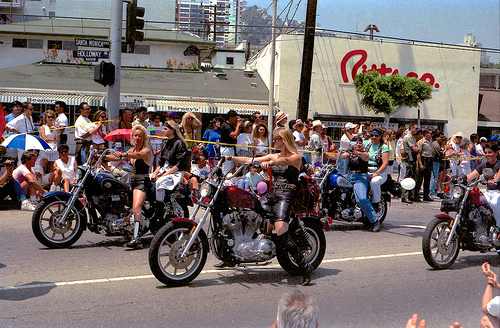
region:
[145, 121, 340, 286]
a woman riding a motorcycle.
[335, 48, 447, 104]
a sign for a store.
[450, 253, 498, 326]
a pair of hands clapping.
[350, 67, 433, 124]
a tree with lots of green leaves.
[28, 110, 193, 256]
a woman riding a harley.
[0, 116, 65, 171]
a blue and white umbrella.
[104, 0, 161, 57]
a black traffic signal.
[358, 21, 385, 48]
an object on top of a roof.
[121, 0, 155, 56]
a traffic light on the side of a road.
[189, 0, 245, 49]
the top of a building.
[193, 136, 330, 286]
woman riding red motorcycle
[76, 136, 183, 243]
woman riding blue motorcycle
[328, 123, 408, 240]
couple riding blue motorcycle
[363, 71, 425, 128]
small green leafy tree in background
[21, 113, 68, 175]
person holding blue and white umbrella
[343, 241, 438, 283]
white line in the street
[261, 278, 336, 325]
back of guys balding head with gray hair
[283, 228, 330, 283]
woman wearing tall black boots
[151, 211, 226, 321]
silver wheel inside of black tire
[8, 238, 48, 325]
shadow of someone standing in the street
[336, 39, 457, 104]
the letters are red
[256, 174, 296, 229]
woman is wearing skirt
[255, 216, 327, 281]
woman wearing black boots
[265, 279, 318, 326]
man's hair is gray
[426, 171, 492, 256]
the motorcycle is red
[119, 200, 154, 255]
woman wearing cowboy boots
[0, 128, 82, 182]
person holding blue and white umbrella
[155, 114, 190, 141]
a person wearing bandana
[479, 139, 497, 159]
the person is smiling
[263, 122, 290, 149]
woman is wearing sunglasses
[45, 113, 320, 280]
women on motorcycles going slow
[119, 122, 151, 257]
blonde in leather and boots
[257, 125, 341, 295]
blonde in leather and sunglasses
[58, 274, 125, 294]
white line in the middle of the road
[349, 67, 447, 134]
green tree on the side of the road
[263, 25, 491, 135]
white building on the side of the road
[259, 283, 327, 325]
top of a balding guy's head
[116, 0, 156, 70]
street light on a pole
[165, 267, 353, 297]
shadow of a motorcycle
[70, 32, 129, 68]
street signs on a pole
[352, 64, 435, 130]
Single green tree in front of a store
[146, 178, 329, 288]
Red motorcycle with silver motor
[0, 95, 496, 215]
Audience along side of street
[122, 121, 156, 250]
Blonde woman riding a blue motorcycle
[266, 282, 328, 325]
The head of a man with a balding spot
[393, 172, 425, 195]
White balloon being held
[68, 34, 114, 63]
Street-name signs on a traffic post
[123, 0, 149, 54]
Traffic lights on a pole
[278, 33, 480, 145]
Storefront with large red letters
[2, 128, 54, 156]
Blue and white umbrella